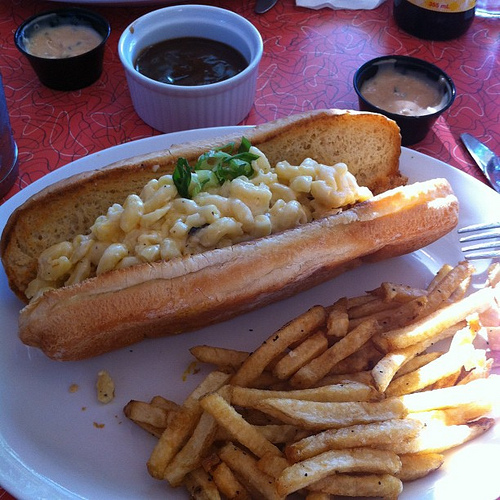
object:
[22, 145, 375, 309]
macaroni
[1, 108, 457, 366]
bun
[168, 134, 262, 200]
garnish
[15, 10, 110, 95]
cup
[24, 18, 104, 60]
sauce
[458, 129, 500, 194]
knife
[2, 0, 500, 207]
table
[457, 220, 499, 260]
fork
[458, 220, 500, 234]
prong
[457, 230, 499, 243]
prong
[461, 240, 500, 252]
prong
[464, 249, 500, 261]
prong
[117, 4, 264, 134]
cup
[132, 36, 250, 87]
sauce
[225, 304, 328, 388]
fry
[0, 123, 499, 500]
plate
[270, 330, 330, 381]
fry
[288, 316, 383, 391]
fry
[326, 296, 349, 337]
fry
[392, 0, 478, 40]
bottle